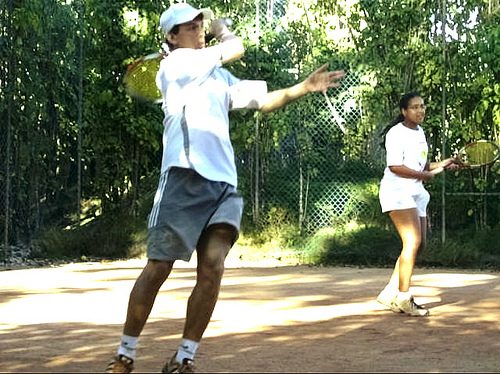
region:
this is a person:
[353, 80, 453, 313]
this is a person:
[94, 8, 259, 372]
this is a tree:
[20, 25, 87, 239]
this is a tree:
[71, 33, 145, 240]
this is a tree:
[267, 38, 341, 236]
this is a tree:
[331, 16, 436, 253]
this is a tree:
[432, 19, 482, 261]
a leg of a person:
[105, 161, 190, 363]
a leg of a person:
[161, 211, 245, 371]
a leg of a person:
[358, 178, 445, 326]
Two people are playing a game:
[80, 0, 496, 371]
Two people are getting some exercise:
[83, 0, 494, 351]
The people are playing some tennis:
[70, 2, 495, 372]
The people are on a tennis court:
[52, 0, 488, 370]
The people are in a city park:
[71, 5, 481, 350]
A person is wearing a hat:
[85, 0, 275, 370]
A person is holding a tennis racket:
[96, 0, 367, 360]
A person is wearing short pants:
[116, 0, 351, 352]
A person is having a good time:
[35, 3, 353, 343]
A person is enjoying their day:
[91, 11, 360, 352]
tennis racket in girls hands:
[421, 132, 498, 187]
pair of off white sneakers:
[359, 274, 441, 322]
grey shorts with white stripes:
[130, 163, 260, 266]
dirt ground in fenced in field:
[0, 236, 496, 372]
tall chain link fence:
[185, 0, 499, 266]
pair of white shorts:
[368, 174, 438, 221]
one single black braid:
[366, 90, 431, 139]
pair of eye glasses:
[403, 98, 430, 118]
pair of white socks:
[100, 320, 212, 365]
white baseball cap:
[151, 0, 220, 40]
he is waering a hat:
[160, 4, 209, 29]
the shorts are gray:
[172, 198, 189, 244]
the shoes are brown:
[98, 347, 129, 372]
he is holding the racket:
[199, 9, 237, 40]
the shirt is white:
[199, 104, 217, 138]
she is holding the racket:
[429, 155, 449, 185]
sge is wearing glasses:
[409, 100, 428, 116]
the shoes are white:
[384, 288, 424, 323]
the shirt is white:
[391, 136, 409, 152]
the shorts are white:
[385, 184, 402, 201]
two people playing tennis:
[91, 4, 468, 372]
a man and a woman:
[108, 3, 497, 372]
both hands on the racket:
[408, 149, 470, 195]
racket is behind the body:
[103, 0, 255, 120]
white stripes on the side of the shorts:
[138, 175, 175, 231]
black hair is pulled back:
[375, 92, 420, 148]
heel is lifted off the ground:
[370, 290, 392, 314]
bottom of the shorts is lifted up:
[200, 205, 243, 254]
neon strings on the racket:
[461, 139, 496, 166]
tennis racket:
[422, 133, 497, 180]